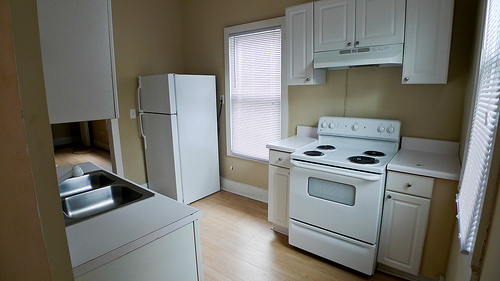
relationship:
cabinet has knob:
[283, 1, 328, 86] [305, 76, 311, 82]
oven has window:
[288, 158, 386, 246] [307, 175, 357, 207]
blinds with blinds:
[224, 16, 289, 164] [228, 25, 281, 164]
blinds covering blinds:
[228, 25, 281, 164] [224, 16, 289, 164]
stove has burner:
[287, 114, 402, 276] [346, 155, 377, 165]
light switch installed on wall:
[129, 108, 136, 120] [110, 0, 182, 186]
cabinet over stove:
[313, 0, 355, 55] [287, 114, 402, 276]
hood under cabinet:
[312, 42, 403, 71] [313, 0, 355, 55]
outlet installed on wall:
[219, 93, 224, 105] [182, 0, 480, 189]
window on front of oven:
[307, 175, 357, 207] [288, 158, 386, 246]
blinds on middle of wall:
[224, 16, 289, 164] [182, 0, 480, 189]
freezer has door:
[136, 72, 217, 113] [136, 72, 177, 114]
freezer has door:
[136, 73, 220, 204] [137, 111, 185, 204]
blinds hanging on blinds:
[228, 25, 281, 164] [224, 16, 289, 164]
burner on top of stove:
[346, 155, 377, 165] [287, 114, 402, 276]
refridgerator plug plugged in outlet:
[219, 98, 224, 103] [219, 93, 224, 105]